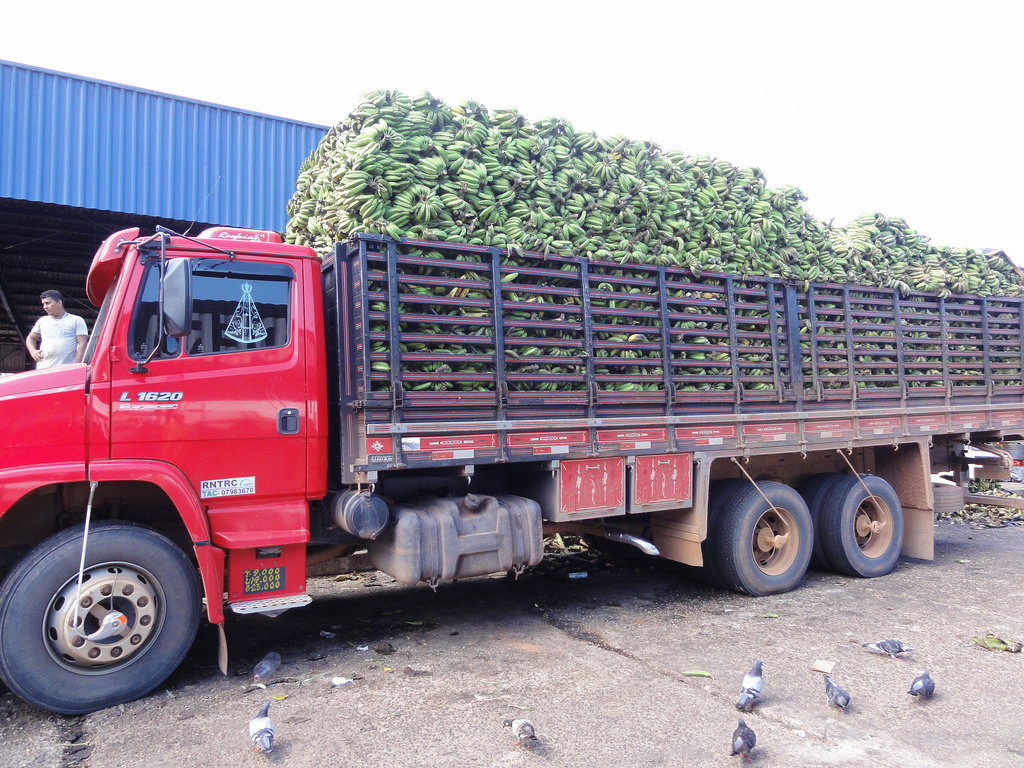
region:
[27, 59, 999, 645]
The red truck is carrying bananas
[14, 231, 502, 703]
The man is standing behind the truck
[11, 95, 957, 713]
The truck has black tires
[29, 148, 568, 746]
The truck has a red door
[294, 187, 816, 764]
The birds are near the truck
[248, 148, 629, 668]
The truck has a black gas tank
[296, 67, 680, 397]
The bananas are green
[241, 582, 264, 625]
The man is wearing a white shirt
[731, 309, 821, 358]
banana in the back of the truck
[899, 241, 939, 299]
banana in the back of the truck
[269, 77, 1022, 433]
large bunch of banans in trailer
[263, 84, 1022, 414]
banana bunches are green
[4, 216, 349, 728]
truck bed is red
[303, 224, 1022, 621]
trailer behind red truck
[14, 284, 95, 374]
man standing next to truck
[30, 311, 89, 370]
man wearing white shirt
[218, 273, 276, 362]
drawing on driver side window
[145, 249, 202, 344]
large side mirror on driver side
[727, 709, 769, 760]
pigeon on ground walking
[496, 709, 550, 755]
pigeon on ground is feeding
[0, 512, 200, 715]
A black tire on a truck.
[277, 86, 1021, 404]
A pile of bananas.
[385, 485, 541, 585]
A device on a truck.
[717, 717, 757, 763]
A small bird near a truck.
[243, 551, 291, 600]
A license plate on a truck.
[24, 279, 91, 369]
A man near a truck.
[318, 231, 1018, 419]
A blue metal rail.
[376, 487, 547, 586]
A metal crank shaft.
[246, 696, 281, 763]
A bird near a cab.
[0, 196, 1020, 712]
a large red truck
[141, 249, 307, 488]
a door on the truck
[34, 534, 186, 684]
a large tire on the truck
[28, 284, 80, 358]
a person in a white shirt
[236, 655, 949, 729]
pigeons on the ground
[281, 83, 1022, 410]
large load of green banana bunches on truck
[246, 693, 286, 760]
pigeon standing on concrete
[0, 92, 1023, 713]
semi truck carrying bananas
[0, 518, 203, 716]
front tire of semi truck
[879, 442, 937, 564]
mud flap of rear tires on semi truck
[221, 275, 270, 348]
decoration on drivers window of semi truck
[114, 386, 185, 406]
emblem on drivers door of semi truck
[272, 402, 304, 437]
door handle to open door of truck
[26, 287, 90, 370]
the man is standing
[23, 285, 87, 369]
the man wearing a short sleeved shirt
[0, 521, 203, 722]
the tire is large and black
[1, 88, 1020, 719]
the bananas in the bed of the red truck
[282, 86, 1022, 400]
the bunches of bananas are green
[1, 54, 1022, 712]
the blue building near the red truck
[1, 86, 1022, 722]
the green bananas and the large red truck